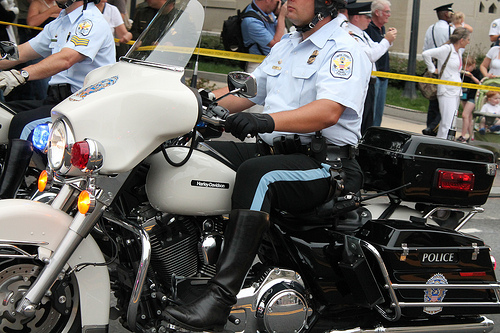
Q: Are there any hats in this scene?
A: Yes, there is a hat.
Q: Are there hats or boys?
A: Yes, there is a hat.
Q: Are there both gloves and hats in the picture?
A: Yes, there are both a hat and gloves.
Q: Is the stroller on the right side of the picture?
A: Yes, the stroller is on the right of the image.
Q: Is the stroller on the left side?
A: No, the stroller is on the right of the image.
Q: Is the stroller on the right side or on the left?
A: The stroller is on the right of the image.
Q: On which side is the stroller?
A: The stroller is on the right of the image.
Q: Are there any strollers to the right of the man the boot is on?
A: Yes, there is a stroller to the right of the man.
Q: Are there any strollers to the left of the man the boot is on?
A: No, the stroller is to the right of the man.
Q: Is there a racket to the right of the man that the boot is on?
A: No, there is a stroller to the right of the man.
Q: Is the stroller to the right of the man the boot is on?
A: Yes, the stroller is to the right of the man.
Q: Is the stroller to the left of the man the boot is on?
A: No, the stroller is to the right of the man.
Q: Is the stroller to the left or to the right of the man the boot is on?
A: The stroller is to the right of the man.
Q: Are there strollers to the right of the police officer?
A: Yes, there is a stroller to the right of the police officer.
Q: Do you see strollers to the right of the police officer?
A: Yes, there is a stroller to the right of the police officer.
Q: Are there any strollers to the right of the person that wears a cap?
A: Yes, there is a stroller to the right of the police officer.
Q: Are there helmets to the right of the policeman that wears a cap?
A: No, there is a stroller to the right of the policeman.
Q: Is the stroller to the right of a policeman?
A: Yes, the stroller is to the right of a policeman.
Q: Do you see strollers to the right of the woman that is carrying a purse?
A: Yes, there is a stroller to the right of the woman.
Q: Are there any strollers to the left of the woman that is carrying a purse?
A: No, the stroller is to the right of the woman.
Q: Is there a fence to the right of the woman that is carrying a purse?
A: No, there is a stroller to the right of the woman.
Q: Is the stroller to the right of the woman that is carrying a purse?
A: Yes, the stroller is to the right of the woman.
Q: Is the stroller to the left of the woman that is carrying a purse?
A: No, the stroller is to the right of the woman.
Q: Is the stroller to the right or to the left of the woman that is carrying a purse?
A: The stroller is to the right of the woman.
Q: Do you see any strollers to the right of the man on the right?
A: Yes, there is a stroller to the right of the man.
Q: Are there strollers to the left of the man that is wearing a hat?
A: No, the stroller is to the right of the man.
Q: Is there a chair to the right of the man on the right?
A: No, there is a stroller to the right of the man.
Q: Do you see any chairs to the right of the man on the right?
A: No, there is a stroller to the right of the man.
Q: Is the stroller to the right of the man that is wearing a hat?
A: Yes, the stroller is to the right of the man.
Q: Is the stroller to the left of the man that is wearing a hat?
A: No, the stroller is to the right of the man.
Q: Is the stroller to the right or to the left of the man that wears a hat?
A: The stroller is to the right of the man.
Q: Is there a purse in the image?
A: Yes, there is a purse.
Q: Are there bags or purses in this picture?
A: Yes, there is a purse.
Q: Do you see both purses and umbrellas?
A: No, there is a purse but no umbrellas.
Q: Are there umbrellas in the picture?
A: No, there are no umbrellas.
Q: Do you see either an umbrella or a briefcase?
A: No, there are no umbrellas or briefcases.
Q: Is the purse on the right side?
A: Yes, the purse is on the right of the image.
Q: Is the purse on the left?
A: No, the purse is on the right of the image.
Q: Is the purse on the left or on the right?
A: The purse is on the right of the image.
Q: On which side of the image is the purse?
A: The purse is on the right of the image.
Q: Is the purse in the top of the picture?
A: Yes, the purse is in the top of the image.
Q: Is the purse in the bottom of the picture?
A: No, the purse is in the top of the image.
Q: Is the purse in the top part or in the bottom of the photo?
A: The purse is in the top of the image.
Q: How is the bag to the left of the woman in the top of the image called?
A: The bag is a purse.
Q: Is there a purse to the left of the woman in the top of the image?
A: Yes, there is a purse to the left of the woman.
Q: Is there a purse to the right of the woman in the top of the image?
A: No, the purse is to the left of the woman.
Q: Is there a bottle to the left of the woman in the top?
A: No, there is a purse to the left of the woman.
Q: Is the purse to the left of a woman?
A: Yes, the purse is to the left of a woman.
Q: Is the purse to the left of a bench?
A: No, the purse is to the left of a woman.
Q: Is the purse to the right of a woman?
A: No, the purse is to the left of a woman.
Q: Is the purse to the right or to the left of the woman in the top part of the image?
A: The purse is to the left of the woman.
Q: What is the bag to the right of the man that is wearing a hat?
A: The bag is a purse.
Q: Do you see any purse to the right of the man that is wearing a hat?
A: Yes, there is a purse to the right of the man.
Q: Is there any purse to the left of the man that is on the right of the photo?
A: No, the purse is to the right of the man.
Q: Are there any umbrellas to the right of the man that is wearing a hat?
A: No, there is a purse to the right of the man.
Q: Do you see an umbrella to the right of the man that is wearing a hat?
A: No, there is a purse to the right of the man.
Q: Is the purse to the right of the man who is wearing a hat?
A: Yes, the purse is to the right of the man.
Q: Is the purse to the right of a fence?
A: No, the purse is to the right of the man.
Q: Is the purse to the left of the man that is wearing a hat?
A: No, the purse is to the right of the man.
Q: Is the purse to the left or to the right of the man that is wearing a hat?
A: The purse is to the right of the man.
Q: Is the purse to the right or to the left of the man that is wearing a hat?
A: The purse is to the right of the man.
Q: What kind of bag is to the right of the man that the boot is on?
A: The bag is a purse.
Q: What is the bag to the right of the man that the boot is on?
A: The bag is a purse.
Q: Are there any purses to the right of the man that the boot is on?
A: Yes, there is a purse to the right of the man.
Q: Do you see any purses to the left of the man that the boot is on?
A: No, the purse is to the right of the man.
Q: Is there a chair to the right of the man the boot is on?
A: No, there is a purse to the right of the man.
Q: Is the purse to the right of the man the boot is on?
A: Yes, the purse is to the right of the man.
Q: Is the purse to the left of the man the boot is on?
A: No, the purse is to the right of the man.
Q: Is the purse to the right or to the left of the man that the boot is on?
A: The purse is to the right of the man.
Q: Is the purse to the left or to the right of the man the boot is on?
A: The purse is to the right of the man.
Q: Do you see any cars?
A: No, there are no cars.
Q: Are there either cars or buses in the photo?
A: No, there are no cars or buses.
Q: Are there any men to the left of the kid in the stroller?
A: Yes, there is a man to the left of the child.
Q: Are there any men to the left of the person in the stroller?
A: Yes, there is a man to the left of the child.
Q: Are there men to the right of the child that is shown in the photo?
A: No, the man is to the left of the child.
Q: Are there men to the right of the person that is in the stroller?
A: No, the man is to the left of the child.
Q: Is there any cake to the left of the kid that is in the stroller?
A: No, there is a man to the left of the child.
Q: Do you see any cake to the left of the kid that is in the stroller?
A: No, there is a man to the left of the child.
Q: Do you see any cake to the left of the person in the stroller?
A: No, there is a man to the left of the child.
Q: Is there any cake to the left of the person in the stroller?
A: No, there is a man to the left of the child.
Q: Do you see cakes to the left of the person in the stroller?
A: No, there is a man to the left of the child.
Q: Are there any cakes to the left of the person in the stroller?
A: No, there is a man to the left of the child.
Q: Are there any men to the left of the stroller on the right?
A: Yes, there is a man to the left of the stroller.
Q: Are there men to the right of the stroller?
A: No, the man is to the left of the stroller.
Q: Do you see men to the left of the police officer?
A: Yes, there is a man to the left of the police officer.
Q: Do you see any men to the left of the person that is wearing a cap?
A: Yes, there is a man to the left of the police officer.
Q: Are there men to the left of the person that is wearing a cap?
A: Yes, there is a man to the left of the police officer.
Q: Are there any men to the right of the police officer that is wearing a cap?
A: No, the man is to the left of the policeman.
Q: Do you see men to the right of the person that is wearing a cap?
A: No, the man is to the left of the policeman.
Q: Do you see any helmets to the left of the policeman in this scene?
A: No, there is a man to the left of the policeman.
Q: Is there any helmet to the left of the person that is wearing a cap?
A: No, there is a man to the left of the policeman.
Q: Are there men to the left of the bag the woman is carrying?
A: Yes, there is a man to the left of the purse.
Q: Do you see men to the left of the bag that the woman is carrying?
A: Yes, there is a man to the left of the purse.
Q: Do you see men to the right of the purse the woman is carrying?
A: No, the man is to the left of the purse.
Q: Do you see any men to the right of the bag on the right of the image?
A: No, the man is to the left of the purse.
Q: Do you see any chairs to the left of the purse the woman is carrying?
A: No, there is a man to the left of the purse.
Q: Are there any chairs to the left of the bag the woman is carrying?
A: No, there is a man to the left of the purse.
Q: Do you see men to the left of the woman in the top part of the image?
A: Yes, there is a man to the left of the woman.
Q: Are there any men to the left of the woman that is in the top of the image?
A: Yes, there is a man to the left of the woman.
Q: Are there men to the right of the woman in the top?
A: No, the man is to the left of the woman.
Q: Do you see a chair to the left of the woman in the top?
A: No, there is a man to the left of the woman.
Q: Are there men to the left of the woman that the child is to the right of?
A: Yes, there is a man to the left of the woman.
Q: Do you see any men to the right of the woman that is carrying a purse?
A: No, the man is to the left of the woman.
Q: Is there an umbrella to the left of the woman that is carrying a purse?
A: No, there is a man to the left of the woman.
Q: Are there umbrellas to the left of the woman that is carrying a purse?
A: No, there is a man to the left of the woman.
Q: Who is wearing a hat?
A: The man is wearing a hat.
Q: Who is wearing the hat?
A: The man is wearing a hat.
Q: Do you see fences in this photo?
A: No, there are no fences.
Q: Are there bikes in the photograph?
A: Yes, there is a bike.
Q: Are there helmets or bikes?
A: Yes, there is a bike.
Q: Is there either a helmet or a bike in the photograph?
A: Yes, there is a bike.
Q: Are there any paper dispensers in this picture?
A: No, there are no paper dispensers.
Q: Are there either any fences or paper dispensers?
A: No, there are no paper dispensers or fences.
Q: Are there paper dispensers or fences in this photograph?
A: No, there are no paper dispensers or fences.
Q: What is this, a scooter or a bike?
A: This is a bike.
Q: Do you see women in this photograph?
A: Yes, there is a woman.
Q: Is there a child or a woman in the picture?
A: Yes, there is a woman.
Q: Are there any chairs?
A: No, there are no chairs.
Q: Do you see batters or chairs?
A: No, there are no chairs or batters.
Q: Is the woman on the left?
A: No, the woman is on the right of the image.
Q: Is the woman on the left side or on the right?
A: The woman is on the right of the image.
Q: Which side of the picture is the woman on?
A: The woman is on the right of the image.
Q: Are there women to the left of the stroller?
A: Yes, there is a woman to the left of the stroller.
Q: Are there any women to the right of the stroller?
A: No, the woman is to the left of the stroller.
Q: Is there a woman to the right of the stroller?
A: No, the woman is to the left of the stroller.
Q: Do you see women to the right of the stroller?
A: No, the woman is to the left of the stroller.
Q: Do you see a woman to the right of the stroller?
A: No, the woman is to the left of the stroller.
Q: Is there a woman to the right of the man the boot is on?
A: Yes, there is a woman to the right of the man.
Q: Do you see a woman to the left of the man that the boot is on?
A: No, the woman is to the right of the man.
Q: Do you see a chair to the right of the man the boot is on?
A: No, there is a woman to the right of the man.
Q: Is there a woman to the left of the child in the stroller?
A: Yes, there is a woman to the left of the kid.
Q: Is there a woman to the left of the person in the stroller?
A: Yes, there is a woman to the left of the kid.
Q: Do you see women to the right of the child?
A: No, the woman is to the left of the child.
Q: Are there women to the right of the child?
A: No, the woman is to the left of the child.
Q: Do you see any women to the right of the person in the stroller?
A: No, the woman is to the left of the child.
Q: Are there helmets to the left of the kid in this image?
A: No, there is a woman to the left of the kid.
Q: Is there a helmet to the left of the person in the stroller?
A: No, there is a woman to the left of the kid.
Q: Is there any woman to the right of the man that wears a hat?
A: Yes, there is a woman to the right of the man.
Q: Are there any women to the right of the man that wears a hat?
A: Yes, there is a woman to the right of the man.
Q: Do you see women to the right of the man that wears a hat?
A: Yes, there is a woman to the right of the man.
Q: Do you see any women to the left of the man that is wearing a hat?
A: No, the woman is to the right of the man.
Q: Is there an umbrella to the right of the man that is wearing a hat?
A: No, there is a woman to the right of the man.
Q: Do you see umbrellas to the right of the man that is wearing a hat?
A: No, there is a woman to the right of the man.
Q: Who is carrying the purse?
A: The woman is carrying the purse.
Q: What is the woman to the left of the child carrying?
A: The woman is carrying a purse.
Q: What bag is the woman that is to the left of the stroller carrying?
A: The woman is carrying a purse.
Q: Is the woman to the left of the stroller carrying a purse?
A: Yes, the woman is carrying a purse.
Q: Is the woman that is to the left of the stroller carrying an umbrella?
A: No, the woman is carrying a purse.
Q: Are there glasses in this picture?
A: No, there are no glasses.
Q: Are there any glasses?
A: No, there are no glasses.